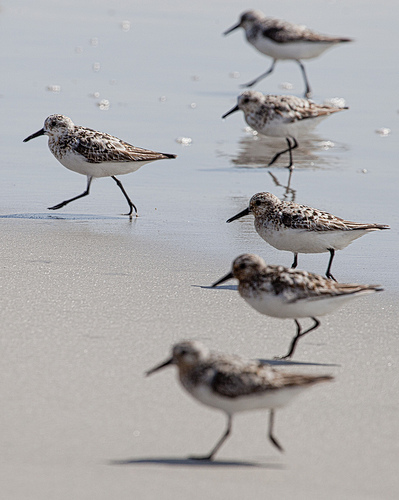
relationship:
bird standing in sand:
[213, 255, 383, 361] [2, 3, 398, 498]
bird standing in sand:
[227, 190, 393, 285] [2, 3, 398, 498]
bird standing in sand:
[221, 86, 349, 171] [2, 3, 398, 498]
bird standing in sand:
[221, 6, 358, 98] [2, 3, 398, 498]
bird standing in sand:
[21, 116, 176, 214] [2, 3, 398, 498]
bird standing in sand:
[143, 334, 336, 463] [2, 3, 398, 498]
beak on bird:
[225, 206, 249, 222] [227, 190, 393, 285]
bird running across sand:
[221, 6, 358, 98] [2, 3, 398, 498]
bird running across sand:
[221, 86, 349, 171] [2, 3, 398, 498]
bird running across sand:
[227, 190, 393, 285] [2, 3, 398, 498]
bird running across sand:
[211, 252, 387, 362] [2, 3, 398, 498]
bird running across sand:
[143, 334, 336, 463] [2, 3, 398, 498]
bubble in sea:
[175, 136, 190, 145] [0, 0, 399, 282]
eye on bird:
[49, 123, 59, 131] [33, 105, 181, 187]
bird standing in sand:
[21, 116, 176, 214] [23, 159, 383, 480]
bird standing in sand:
[221, 86, 349, 171] [9, 169, 366, 316]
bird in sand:
[221, 6, 358, 98] [2, 3, 398, 498]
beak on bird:
[23, 129, 44, 141] [21, 116, 176, 214]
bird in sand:
[227, 190, 393, 285] [2, 3, 398, 498]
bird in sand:
[221, 86, 349, 171] [2, 3, 398, 498]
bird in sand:
[22, 114, 176, 222] [2, 3, 398, 498]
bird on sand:
[21, 116, 176, 214] [2, 3, 398, 498]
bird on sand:
[221, 6, 358, 98] [2, 3, 398, 498]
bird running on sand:
[22, 114, 176, 222] [2, 3, 398, 498]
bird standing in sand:
[143, 334, 336, 463] [5, 255, 148, 497]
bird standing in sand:
[179, 103, 336, 181] [0, 68, 397, 497]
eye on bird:
[45, 121, 59, 132] [143, 334, 336, 463]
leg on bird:
[102, 169, 139, 219] [20, 99, 180, 234]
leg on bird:
[49, 172, 94, 213] [21, 116, 176, 214]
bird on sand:
[22, 114, 176, 222] [5, 158, 398, 497]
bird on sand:
[221, 86, 349, 171] [0, 208, 398, 500]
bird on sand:
[21, 116, 176, 214] [0, 208, 398, 500]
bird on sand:
[143, 334, 336, 463] [0, 208, 398, 500]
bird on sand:
[211, 252, 387, 362] [0, 208, 398, 500]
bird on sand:
[217, 186, 393, 286] [0, 208, 398, 500]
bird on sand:
[214, 6, 361, 103] [0, 208, 398, 500]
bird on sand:
[143, 334, 336, 463] [13, 389, 211, 497]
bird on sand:
[213, 255, 383, 361] [19, 49, 384, 479]